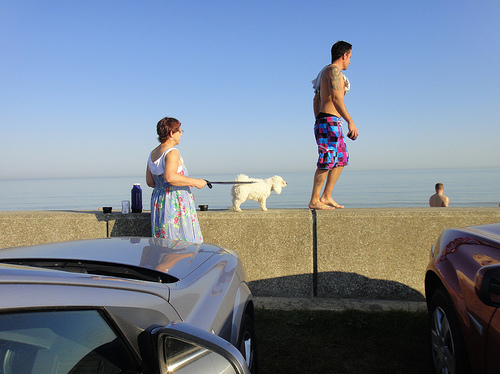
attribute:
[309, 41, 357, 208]
man — shirtless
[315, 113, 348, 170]
shorts — purple, blue, colorful, red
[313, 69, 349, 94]
shirt — white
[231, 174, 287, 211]
dog — small, white, poodle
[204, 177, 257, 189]
leash — black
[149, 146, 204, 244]
dress — blue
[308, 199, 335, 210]
foot — bare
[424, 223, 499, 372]
car — red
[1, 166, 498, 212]
water — a body, still, calm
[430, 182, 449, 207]
man — shirtless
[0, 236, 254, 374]
car — parked, gray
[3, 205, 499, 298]
wall — short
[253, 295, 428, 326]
sidewalk — split